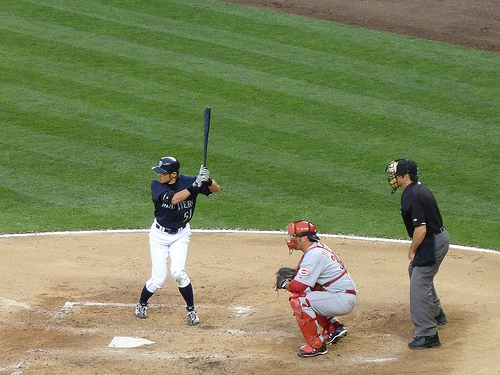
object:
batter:
[134, 156, 221, 327]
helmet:
[151, 157, 180, 175]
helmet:
[281, 220, 319, 256]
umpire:
[382, 158, 450, 348]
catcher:
[273, 220, 359, 359]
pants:
[144, 217, 192, 294]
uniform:
[286, 242, 358, 351]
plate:
[108, 335, 156, 348]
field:
[0, 1, 499, 253]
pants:
[406, 229, 450, 337]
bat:
[200, 107, 212, 188]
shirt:
[150, 175, 212, 229]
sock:
[178, 284, 196, 308]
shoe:
[134, 301, 148, 319]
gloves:
[191, 172, 209, 188]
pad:
[288, 291, 323, 350]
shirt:
[398, 182, 444, 239]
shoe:
[406, 331, 440, 349]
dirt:
[217, 0, 500, 53]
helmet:
[383, 158, 419, 195]